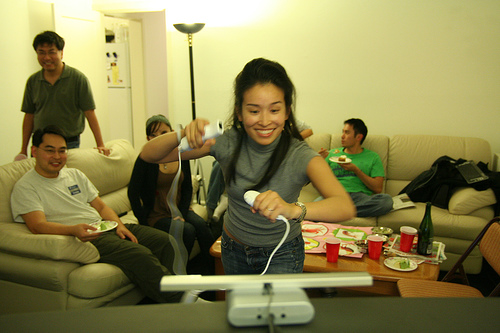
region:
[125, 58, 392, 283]
A girl playing the wii.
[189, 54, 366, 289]
A girl with long black hair.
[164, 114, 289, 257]
A white wii controller.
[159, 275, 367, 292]
A wii sensor bar.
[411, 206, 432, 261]
A green glass bottle.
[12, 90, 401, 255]
People sitting down.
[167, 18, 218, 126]
A black floor lamp.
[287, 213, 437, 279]
A wooden coffee table.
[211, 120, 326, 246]
Woman wearing a shirt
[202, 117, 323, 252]
Woman is wearing a shirt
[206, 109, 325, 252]
Woman is wearing a gray shirt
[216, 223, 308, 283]
Woman wearing blue pants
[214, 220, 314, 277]
Woman is wearing blue pants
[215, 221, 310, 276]
Woman is wearing jeans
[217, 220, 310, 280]
Woman wearing blue jeans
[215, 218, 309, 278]
Woman is wearing blue jeans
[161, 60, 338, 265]
a woman holding two Wii remotes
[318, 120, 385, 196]
a man wearing a green shirt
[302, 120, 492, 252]
a man sitting on a white couch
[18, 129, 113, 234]
a man wearing a white shirt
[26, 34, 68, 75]
a man with black hair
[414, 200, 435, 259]
a green colored bottle of wine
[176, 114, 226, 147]
a white Wii controller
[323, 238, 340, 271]
a red plastic cup on a table top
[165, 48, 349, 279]
a woman holding wii remotes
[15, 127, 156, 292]
a man sitting on a sofa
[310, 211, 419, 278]
three red cups on a table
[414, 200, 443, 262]
a green glass bottle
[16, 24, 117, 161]
a man standing behind a sofa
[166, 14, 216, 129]
a light behind a sofa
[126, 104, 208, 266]
a woman sitting on a sofa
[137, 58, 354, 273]
woman with long black hair and gold hoop earrings hold white game remote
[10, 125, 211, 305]
man in white shirt and dark pants holds small white plate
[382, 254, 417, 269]
green food with small round plate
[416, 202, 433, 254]
empty green bottle on wood table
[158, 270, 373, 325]
white video game motion detector on black tv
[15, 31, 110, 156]
man with dark hair wears green polo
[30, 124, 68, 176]
man wears black glasses on his round face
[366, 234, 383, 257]
empty red plastic cup on wooden table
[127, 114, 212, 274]
woman wearing green headband on beige couch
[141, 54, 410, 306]
A woman playing the wii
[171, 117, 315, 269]
A white wii controller.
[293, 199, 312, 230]
A silver wristwatch.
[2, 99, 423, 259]
people sitting down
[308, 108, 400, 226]
A man sitting on the sofa.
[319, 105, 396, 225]
A man with black hair.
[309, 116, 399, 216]
A man wearing a green shirt.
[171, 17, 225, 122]
A black floor lamp lit up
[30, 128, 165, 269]
A man holding a plate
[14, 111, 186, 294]
A man wearing glasses.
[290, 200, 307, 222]
a woman's gray watch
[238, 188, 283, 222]
a white game controller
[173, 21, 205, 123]
a tall black lamp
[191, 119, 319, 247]
a woman's gray short sleeve shirt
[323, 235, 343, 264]
a red cup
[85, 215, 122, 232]
a small white plate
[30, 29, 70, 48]
a man's short cut black hair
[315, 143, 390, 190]
a man's short sleeve green shirt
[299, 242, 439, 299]
a brown table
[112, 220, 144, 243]
the hand of a man